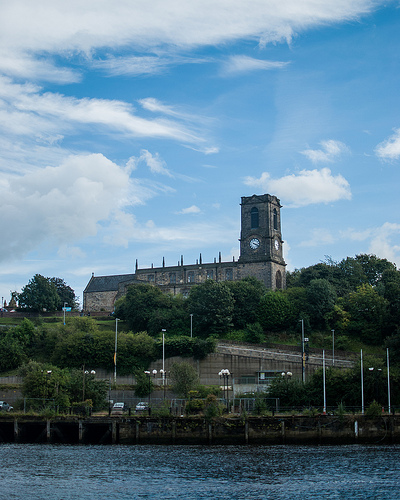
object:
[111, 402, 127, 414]
car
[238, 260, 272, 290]
walls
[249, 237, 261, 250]
clock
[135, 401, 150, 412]
cars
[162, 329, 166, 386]
post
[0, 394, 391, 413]
lot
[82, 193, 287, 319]
building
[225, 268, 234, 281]
window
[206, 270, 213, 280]
window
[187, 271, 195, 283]
window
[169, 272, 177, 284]
window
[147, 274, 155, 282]
window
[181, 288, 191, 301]
window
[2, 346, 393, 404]
wall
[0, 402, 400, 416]
area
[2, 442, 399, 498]
water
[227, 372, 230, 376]
globe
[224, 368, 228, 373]
globe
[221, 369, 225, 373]
globe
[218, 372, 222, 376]
globe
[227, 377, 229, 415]
post